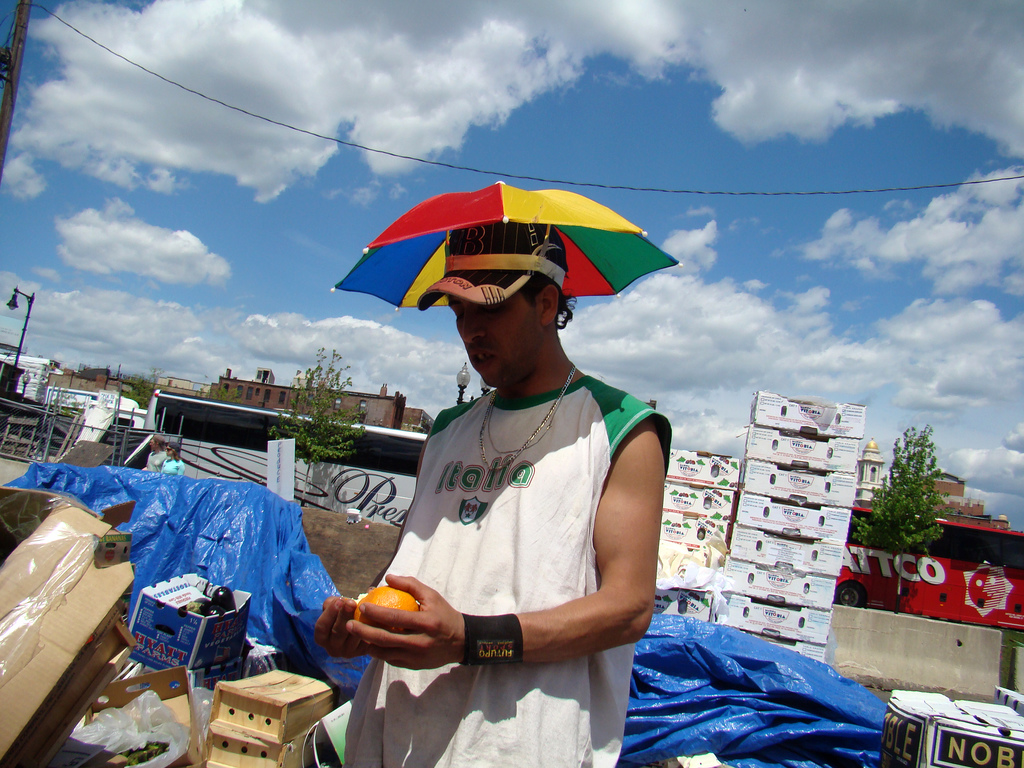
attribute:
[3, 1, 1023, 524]
clouds — white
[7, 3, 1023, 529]
sky — blue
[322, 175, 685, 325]
visor — worn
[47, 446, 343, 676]
tarp — blue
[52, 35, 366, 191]
clouds — white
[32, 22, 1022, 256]
sky — blue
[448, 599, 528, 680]
band — black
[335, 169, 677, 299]
umbrella — small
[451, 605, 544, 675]
wristband — black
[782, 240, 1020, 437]
sky — blue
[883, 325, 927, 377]
clouds — white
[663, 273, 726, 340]
clouds — white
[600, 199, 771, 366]
sky — blue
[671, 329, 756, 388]
clouds — white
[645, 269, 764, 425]
sky — blue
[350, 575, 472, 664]
hand — man's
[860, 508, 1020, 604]
bus — red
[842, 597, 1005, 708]
barriers — concrete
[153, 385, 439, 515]
bus — white, walking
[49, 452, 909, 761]
tarps — blue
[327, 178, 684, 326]
hat — the man's, umbrella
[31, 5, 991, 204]
wire — utility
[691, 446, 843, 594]
boxes — white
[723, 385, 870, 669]
supplies — tall stack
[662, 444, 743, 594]
supplies — tall stack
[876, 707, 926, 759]
signing — black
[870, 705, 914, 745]
letters — gold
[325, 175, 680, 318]
umbrella — small, colored, wearable, colorful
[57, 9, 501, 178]
clouds — large, white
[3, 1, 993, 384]
sky — bright blue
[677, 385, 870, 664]
boxes — stacked, white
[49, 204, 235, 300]
clouds — white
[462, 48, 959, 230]
sky — blue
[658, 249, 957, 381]
clouds — white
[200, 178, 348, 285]
sky — blue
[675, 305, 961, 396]
clouds — white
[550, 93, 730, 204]
sky — blue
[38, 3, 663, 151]
clouds — white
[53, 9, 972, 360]
sky — blue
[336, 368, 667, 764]
top — white, tank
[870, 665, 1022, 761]
box — white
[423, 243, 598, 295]
strap — white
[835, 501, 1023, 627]
bus — red